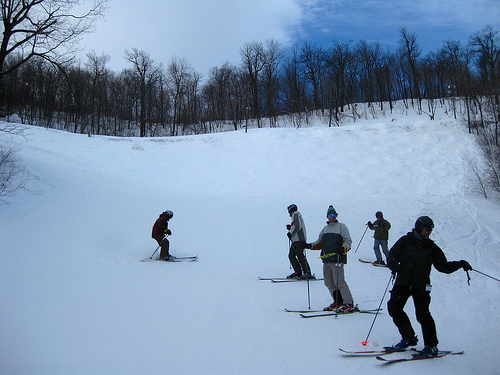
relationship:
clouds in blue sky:
[3, 1, 312, 77] [0, 0, 500, 113]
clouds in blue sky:
[3, 1, 500, 118] [292, 0, 499, 72]